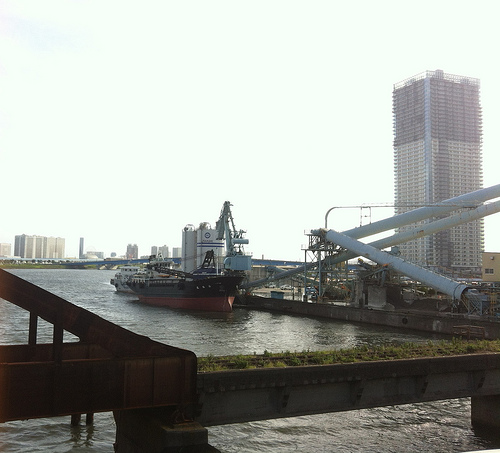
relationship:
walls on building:
[181, 228, 195, 256] [393, 73, 480, 281]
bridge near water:
[0, 267, 499, 451] [2, 267, 452, 355]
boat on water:
[112, 240, 266, 316] [140, 289, 267, 354]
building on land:
[14, 233, 66, 259] [1, 260, 176, 270]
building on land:
[77, 237, 86, 259] [1, 260, 176, 270]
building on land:
[1, 240, 12, 257] [1, 260, 176, 270]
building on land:
[150, 245, 157, 257] [1, 260, 176, 270]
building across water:
[14, 233, 66, 259] [1, 267, 491, 449]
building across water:
[77, 237, 86, 259] [1, 267, 491, 449]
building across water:
[1, 240, 12, 257] [1, 267, 491, 449]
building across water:
[150, 245, 157, 257] [1, 267, 491, 449]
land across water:
[211, 330, 480, 360] [65, 261, 352, 338]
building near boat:
[182, 225, 221, 267] [112, 255, 248, 322]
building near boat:
[392, 67, 486, 277] [112, 255, 248, 322]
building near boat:
[15, 233, 64, 260] [112, 255, 248, 322]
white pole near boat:
[323, 229, 490, 312] [126, 249, 243, 316]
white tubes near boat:
[338, 186, 498, 249] [126, 249, 243, 316]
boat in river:
[125, 249, 244, 315] [3, 268, 496, 450]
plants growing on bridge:
[200, 339, 495, 374] [197, 334, 498, 431]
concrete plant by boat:
[147, 202, 253, 291] [125, 249, 244, 315]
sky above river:
[5, 4, 497, 260] [3, 268, 496, 450]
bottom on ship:
[133, 289, 240, 319] [124, 248, 246, 321]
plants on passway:
[200, 339, 495, 374] [189, 340, 499, 376]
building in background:
[14, 233, 66, 259] [13, 224, 325, 288]